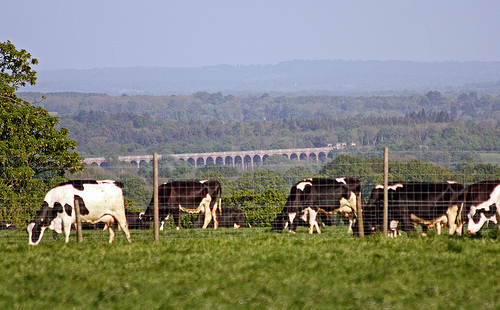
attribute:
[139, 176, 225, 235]
cow — white, black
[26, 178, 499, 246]
cows — grazing, white, black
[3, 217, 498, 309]
field — grassy, green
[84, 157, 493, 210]
trees — green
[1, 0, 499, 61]
sky — blue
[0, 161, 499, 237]
fence — wire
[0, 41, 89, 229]
tree — green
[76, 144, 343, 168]
highway — brown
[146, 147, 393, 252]
poles — wood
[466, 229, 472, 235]
nose — pink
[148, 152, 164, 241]
post — brown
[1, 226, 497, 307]
field — grassy, green